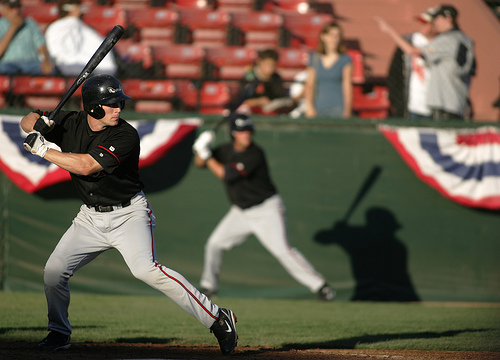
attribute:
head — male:
[80, 77, 129, 127]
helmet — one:
[75, 73, 118, 120]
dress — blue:
[296, 9, 389, 139]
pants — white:
[3, 179, 224, 339]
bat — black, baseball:
[47, 20, 132, 149]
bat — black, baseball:
[36, 27, 131, 134]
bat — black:
[38, 14, 156, 163]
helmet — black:
[76, 78, 145, 138]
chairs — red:
[85, 23, 405, 129]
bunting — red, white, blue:
[374, 116, 496, 246]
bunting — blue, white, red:
[1, 109, 214, 206]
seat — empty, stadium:
[137, 40, 223, 94]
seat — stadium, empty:
[231, 5, 306, 54]